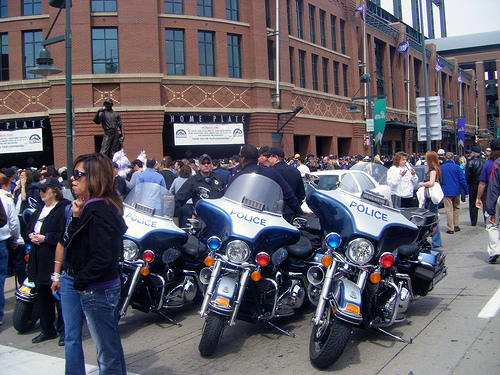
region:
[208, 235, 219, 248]
blue light on motorcycle.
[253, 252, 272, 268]
red light on motorcycle.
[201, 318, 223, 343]
tire made of rubber.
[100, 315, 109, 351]
jeans on the woman.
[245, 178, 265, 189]
windshield on the motorcycle.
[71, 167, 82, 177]
glasses on woman's face.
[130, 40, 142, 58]
wall made of brick.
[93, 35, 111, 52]
window on the building.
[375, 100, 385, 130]
banner near the building.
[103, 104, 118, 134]
statue near the building.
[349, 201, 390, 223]
the word Police in blue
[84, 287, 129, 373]
she is wearing a blue jeans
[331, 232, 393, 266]
the headlights of the police motorcycle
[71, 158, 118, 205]
the head of the woman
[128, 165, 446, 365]
several police on the scene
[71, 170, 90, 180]
she is wearing sunglasses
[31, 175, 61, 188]
this is a blue cap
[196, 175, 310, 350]
a police motorcycle in the middle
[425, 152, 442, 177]
she has a long blond hair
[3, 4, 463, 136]
a huge building in the background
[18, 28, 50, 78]
window of a building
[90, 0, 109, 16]
window of a building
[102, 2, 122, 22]
window of a building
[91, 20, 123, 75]
window of a building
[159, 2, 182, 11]
window of a building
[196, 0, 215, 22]
window of a building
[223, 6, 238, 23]
window of a building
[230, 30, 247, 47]
window of a building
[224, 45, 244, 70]
window of a building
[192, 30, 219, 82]
window of a building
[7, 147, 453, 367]
THE POLICE BIKES ARE SIDE BY SIDE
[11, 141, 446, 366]
THE BIKES ARE PARKED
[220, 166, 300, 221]
THIS IS A WINDSHIELD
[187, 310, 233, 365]
THIS IS A TIRE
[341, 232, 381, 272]
THIS IS A HEADLIGHT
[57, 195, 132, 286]
THE WOMAN IS WEARING A BLACK HOODIE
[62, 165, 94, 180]
THE WOMAN IS WEARING SUNGLASSES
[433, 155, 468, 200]
THE MAN IS WEARING A BLUE JACKET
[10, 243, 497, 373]
THE SHADOWS ARE ON THE GROUND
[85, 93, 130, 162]
THE STATUE STANDS ABOVE THE CROUD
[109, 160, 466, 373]
police motorcycles are parked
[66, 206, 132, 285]
the jacket is black